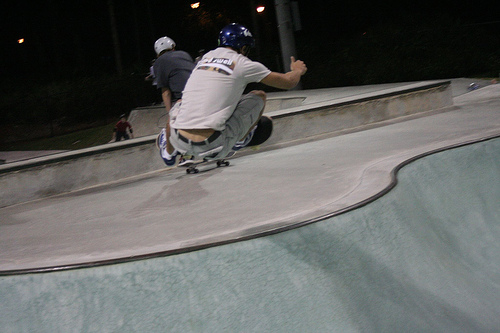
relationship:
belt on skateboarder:
[170, 123, 232, 149] [155, 22, 311, 168]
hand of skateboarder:
[283, 42, 314, 85] [155, 22, 311, 168]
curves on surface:
[331, 137, 390, 174] [288, 144, 378, 247]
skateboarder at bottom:
[189, 34, 305, 151] [128, 118, 181, 162]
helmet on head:
[219, 21, 261, 47] [218, 38, 242, 48]